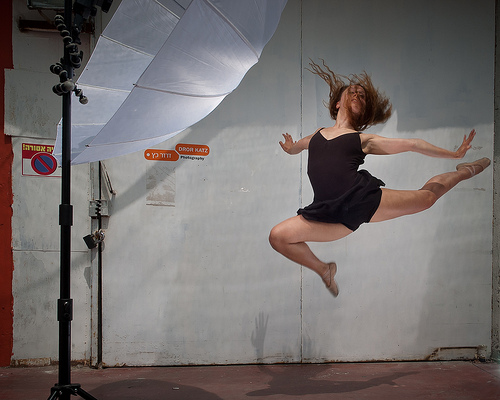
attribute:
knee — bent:
[263, 214, 307, 258]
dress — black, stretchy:
[294, 125, 390, 232]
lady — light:
[265, 67, 497, 298]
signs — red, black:
[114, 127, 249, 241]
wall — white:
[131, 113, 343, 310]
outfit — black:
[292, 127, 388, 232]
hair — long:
[303, 58, 393, 135]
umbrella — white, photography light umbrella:
[57, 0, 291, 169]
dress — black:
[298, 122, 406, 232]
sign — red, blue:
[20, 135, 65, 180]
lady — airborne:
[253, 51, 498, 305]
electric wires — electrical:
[48, 0, 88, 107]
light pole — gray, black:
[45, 0, 100, 400]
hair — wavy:
[375, 93, 407, 120]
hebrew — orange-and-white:
[133, 140, 219, 172]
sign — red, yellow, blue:
[20, 136, 62, 177]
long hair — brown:
[301, 48, 418, 131]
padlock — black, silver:
[79, 227, 106, 252]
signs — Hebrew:
[139, 135, 210, 165]